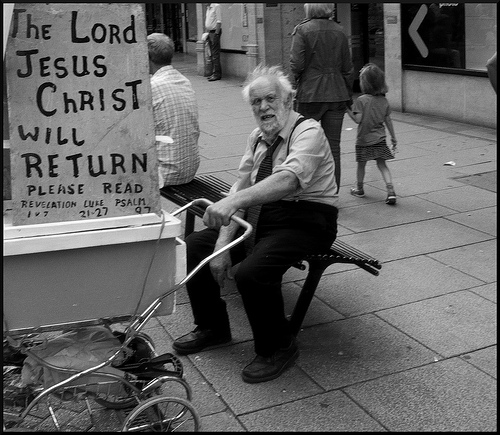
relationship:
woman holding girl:
[287, 2, 357, 200] [345, 62, 398, 205]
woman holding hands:
[287, 2, 357, 200] [341, 76, 361, 116]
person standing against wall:
[196, 0, 231, 85] [221, 2, 257, 67]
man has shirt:
[170, 60, 341, 385] [246, 139, 320, 175]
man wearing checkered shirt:
[146, 22, 203, 193] [147, 62, 207, 187]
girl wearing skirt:
[339, 58, 436, 249] [357, 140, 416, 165]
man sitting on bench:
[170, 60, 341, 385] [303, 240, 381, 277]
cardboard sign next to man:
[0, 0, 163, 229] [163, 25, 382, 318]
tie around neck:
[241, 141, 284, 258] [251, 108, 303, 141]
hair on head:
[233, 61, 293, 98] [238, 60, 297, 140]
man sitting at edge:
[170, 60, 341, 385] [161, 177, 329, 302]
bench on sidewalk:
[173, 171, 373, 286] [109, 62, 499, 429]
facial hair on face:
[252, 113, 287, 133] [238, 73, 286, 132]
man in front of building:
[170, 60, 341, 385] [149, 1, 497, 129]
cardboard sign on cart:
[8, 6, 162, 218] [0, 188, 244, 422]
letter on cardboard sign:
[12, 47, 37, 79] [0, 0, 163, 229]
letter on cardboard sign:
[67, 8, 93, 45] [0, 0, 163, 229]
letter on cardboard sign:
[33, 81, 60, 115] [0, 0, 163, 229]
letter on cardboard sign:
[16, 150, 45, 178] [0, 0, 163, 229]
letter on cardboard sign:
[18, 122, 43, 140] [0, 0, 163, 229]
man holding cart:
[188, 56, 372, 244] [3, 197, 252, 431]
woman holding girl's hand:
[287, 2, 357, 200] [345, 101, 351, 117]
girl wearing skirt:
[345, 62, 398, 205] [346, 135, 403, 171]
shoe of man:
[238, 325, 301, 384] [170, 60, 341, 385]